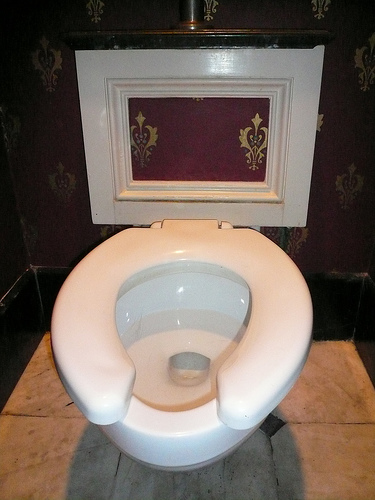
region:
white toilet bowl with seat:
[46, 218, 310, 470]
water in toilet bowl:
[122, 308, 236, 401]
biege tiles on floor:
[1, 317, 374, 497]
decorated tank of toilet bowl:
[75, 29, 323, 225]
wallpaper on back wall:
[2, 4, 370, 279]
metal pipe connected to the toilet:
[175, 2, 209, 28]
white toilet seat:
[57, 224, 310, 430]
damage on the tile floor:
[258, 409, 306, 484]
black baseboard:
[5, 258, 373, 412]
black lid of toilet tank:
[64, 27, 337, 48]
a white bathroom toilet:
[32, 26, 360, 497]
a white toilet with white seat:
[38, 168, 307, 436]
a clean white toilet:
[60, 178, 330, 456]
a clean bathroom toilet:
[35, 178, 334, 495]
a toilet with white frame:
[59, 16, 348, 430]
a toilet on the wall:
[27, 2, 354, 490]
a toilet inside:
[50, 31, 369, 476]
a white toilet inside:
[33, 26, 348, 496]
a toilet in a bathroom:
[44, 10, 362, 498]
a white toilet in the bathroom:
[14, 11, 323, 489]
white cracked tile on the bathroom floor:
[266, 408, 352, 496]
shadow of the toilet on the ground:
[54, 350, 348, 498]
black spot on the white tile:
[244, 399, 297, 442]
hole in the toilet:
[145, 345, 225, 395]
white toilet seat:
[40, 220, 324, 446]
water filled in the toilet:
[100, 283, 274, 436]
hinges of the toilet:
[131, 206, 265, 241]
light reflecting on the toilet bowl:
[139, 274, 199, 316]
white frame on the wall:
[50, 32, 327, 254]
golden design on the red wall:
[116, 106, 168, 173]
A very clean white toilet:
[70, 222, 278, 438]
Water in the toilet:
[159, 344, 213, 386]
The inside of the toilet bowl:
[128, 269, 246, 363]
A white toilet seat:
[74, 226, 311, 393]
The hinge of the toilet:
[138, 200, 239, 240]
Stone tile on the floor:
[290, 364, 367, 487]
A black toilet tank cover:
[69, 27, 343, 57]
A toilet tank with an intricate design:
[77, 46, 316, 217]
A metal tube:
[175, 0, 210, 33]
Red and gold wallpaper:
[0, 19, 91, 239]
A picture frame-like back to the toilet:
[73, 33, 321, 228]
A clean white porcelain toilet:
[45, 216, 314, 469]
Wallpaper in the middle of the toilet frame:
[127, 94, 270, 181]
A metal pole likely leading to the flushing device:
[174, 0, 212, 31]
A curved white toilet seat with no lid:
[49, 219, 314, 429]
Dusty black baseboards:
[0, 264, 373, 412]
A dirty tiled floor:
[0, 329, 374, 498]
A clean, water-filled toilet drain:
[167, 350, 209, 387]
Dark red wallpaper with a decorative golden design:
[0, 2, 373, 299]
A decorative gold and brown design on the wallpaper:
[237, 113, 265, 171]